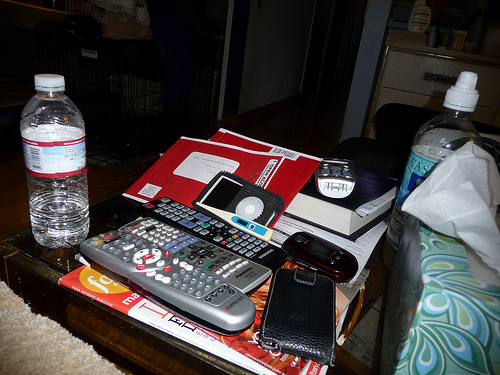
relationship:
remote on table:
[141, 193, 283, 270] [1, 183, 268, 375]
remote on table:
[115, 214, 269, 293] [1, 183, 268, 375]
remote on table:
[83, 232, 256, 334] [1, 183, 268, 375]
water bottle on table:
[22, 65, 92, 249] [1, 183, 268, 375]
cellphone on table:
[280, 230, 358, 283] [1, 183, 268, 375]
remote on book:
[314, 156, 356, 199] [285, 156, 401, 244]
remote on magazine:
[79, 233, 256, 334] [57, 254, 362, 374]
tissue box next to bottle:
[379, 140, 499, 374] [375, 69, 480, 267]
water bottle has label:
[22, 65, 92, 249] [15, 132, 92, 177]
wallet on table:
[255, 264, 340, 369] [1, 183, 268, 375]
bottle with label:
[375, 69, 480, 267] [392, 146, 439, 211]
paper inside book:
[355, 185, 398, 220] [285, 156, 401, 244]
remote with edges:
[314, 156, 356, 199] [315, 181, 359, 198]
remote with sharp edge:
[115, 214, 269, 293] [238, 265, 273, 295]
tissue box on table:
[379, 140, 499, 374] [1, 183, 268, 375]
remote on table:
[79, 233, 256, 334] [1, 183, 268, 375]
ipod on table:
[197, 170, 285, 230] [1, 183, 268, 375]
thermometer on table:
[189, 199, 275, 244] [1, 183, 268, 375]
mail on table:
[207, 127, 313, 228] [1, 183, 268, 375]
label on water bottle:
[15, 132, 92, 177] [22, 65, 92, 249]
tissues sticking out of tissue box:
[400, 132, 499, 268] [379, 140, 499, 374]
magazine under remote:
[57, 254, 362, 374] [79, 233, 256, 334]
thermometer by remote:
[189, 199, 275, 244] [79, 233, 256, 334]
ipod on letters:
[197, 170, 285, 230] [115, 123, 324, 230]